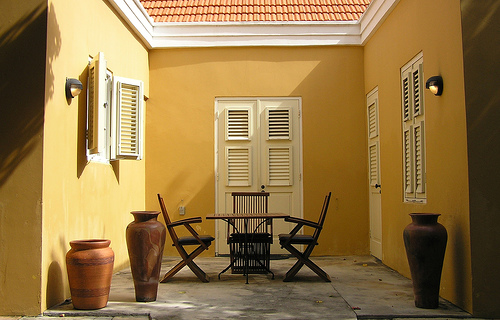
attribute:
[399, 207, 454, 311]
urn — is dark-brown, is tall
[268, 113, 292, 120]
slat — white, wooden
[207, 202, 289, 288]
table — is brown, is wooden, is small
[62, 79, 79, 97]
light — is small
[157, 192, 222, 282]
folding chair — is brown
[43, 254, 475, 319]
concrete patio — is gray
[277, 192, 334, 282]
chair — outdoor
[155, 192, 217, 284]
chair — outdoor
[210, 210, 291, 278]
table — outdoor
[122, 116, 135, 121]
slat — white, wooden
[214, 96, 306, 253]
door — white, is white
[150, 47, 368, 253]
wall — is yellow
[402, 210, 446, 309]
vase — tall, brown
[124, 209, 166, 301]
vase — pictured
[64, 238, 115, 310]
vase — pictured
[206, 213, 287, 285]
table — wooden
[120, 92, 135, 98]
slat — white, wooden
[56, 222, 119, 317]
urn — medium-sized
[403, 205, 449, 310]
vase — pictured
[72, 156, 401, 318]
furniture — outdoor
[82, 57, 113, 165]
window — is white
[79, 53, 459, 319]
patio — is yellow, is exterior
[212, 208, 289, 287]
table — is wooden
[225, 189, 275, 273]
chair — is metal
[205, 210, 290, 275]
table — patio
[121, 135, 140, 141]
slat — wooden, white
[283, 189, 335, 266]
chair — outdoor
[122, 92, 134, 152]
wooden slat — white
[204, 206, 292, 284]
table — is wooden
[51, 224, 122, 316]
vase — rust colored, large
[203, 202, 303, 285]
table — is wooden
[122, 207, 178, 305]
urn — is tall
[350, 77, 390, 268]
door — white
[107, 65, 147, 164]
shutter — open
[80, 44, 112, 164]
shutter — open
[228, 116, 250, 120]
wooden slat — white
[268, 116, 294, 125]
wooden slat — white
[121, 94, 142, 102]
wooden slat — white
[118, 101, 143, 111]
wooden slat — white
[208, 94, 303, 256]
door — white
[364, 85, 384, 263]
door — white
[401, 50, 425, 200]
window — white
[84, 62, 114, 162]
window — white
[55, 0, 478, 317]
patio — exterior view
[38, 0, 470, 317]
walls — yellow